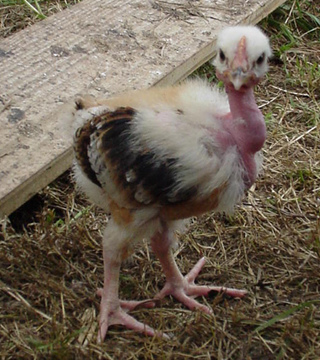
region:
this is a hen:
[62, 15, 284, 353]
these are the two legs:
[84, 242, 210, 345]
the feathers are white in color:
[88, 90, 201, 187]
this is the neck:
[233, 90, 259, 139]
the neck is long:
[237, 90, 258, 143]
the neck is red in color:
[238, 95, 261, 147]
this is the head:
[214, 26, 270, 85]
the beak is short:
[229, 73, 243, 89]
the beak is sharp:
[230, 74, 246, 89]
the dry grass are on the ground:
[14, 255, 85, 349]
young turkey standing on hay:
[61, 19, 298, 335]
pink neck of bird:
[225, 89, 272, 163]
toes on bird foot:
[169, 263, 242, 326]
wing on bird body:
[85, 113, 178, 214]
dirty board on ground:
[10, 109, 54, 220]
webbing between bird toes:
[103, 307, 124, 331]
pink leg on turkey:
[156, 225, 188, 288]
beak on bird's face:
[224, 57, 255, 99]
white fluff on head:
[223, 20, 265, 51]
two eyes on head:
[214, 44, 270, 68]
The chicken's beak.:
[225, 68, 245, 88]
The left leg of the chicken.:
[96, 243, 156, 331]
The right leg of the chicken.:
[153, 226, 230, 322]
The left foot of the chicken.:
[87, 283, 161, 342]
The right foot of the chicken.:
[151, 264, 233, 305]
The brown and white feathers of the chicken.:
[67, 109, 207, 205]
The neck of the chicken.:
[217, 81, 265, 161]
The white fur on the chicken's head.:
[213, 21, 263, 69]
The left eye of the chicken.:
[218, 45, 229, 64]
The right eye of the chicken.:
[254, 46, 267, 67]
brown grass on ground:
[248, 216, 299, 262]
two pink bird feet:
[86, 256, 247, 345]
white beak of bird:
[231, 72, 247, 88]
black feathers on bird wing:
[108, 134, 128, 157]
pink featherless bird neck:
[231, 94, 256, 113]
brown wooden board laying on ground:
[19, 63, 58, 99]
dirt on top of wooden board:
[81, 17, 177, 63]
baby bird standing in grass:
[59, 30, 285, 323]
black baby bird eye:
[250, 46, 271, 68]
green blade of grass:
[297, 18, 316, 30]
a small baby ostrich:
[68, 26, 281, 343]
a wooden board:
[0, 1, 288, 218]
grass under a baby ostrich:
[3, 1, 318, 358]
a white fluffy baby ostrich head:
[212, 23, 273, 87]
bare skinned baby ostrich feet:
[87, 260, 255, 347]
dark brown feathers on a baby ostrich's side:
[100, 106, 151, 200]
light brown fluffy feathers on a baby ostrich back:
[107, 82, 174, 99]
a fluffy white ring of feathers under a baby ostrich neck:
[167, 75, 261, 203]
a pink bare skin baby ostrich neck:
[221, 85, 271, 158]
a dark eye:
[256, 50, 266, 64]